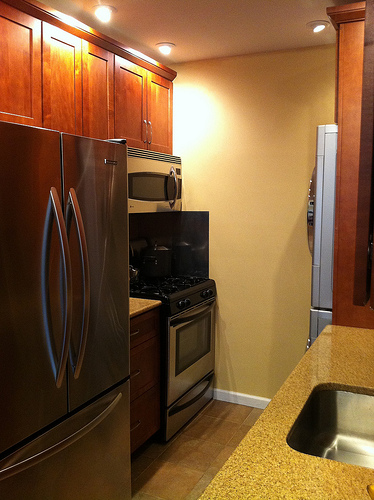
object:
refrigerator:
[0, 122, 130, 495]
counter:
[211, 326, 373, 499]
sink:
[293, 380, 373, 472]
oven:
[163, 279, 217, 442]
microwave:
[124, 149, 186, 214]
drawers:
[125, 317, 161, 445]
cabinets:
[2, 12, 184, 149]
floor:
[137, 402, 255, 500]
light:
[91, 5, 120, 25]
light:
[155, 38, 176, 56]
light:
[309, 21, 328, 34]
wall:
[175, 60, 317, 387]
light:
[176, 82, 236, 165]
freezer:
[4, 380, 147, 498]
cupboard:
[117, 55, 173, 154]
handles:
[143, 120, 148, 143]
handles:
[46, 186, 86, 392]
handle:
[171, 301, 214, 326]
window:
[176, 312, 212, 375]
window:
[133, 173, 169, 200]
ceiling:
[57, 3, 337, 60]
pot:
[140, 245, 172, 278]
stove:
[135, 270, 205, 296]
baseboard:
[213, 387, 266, 410]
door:
[169, 302, 216, 401]